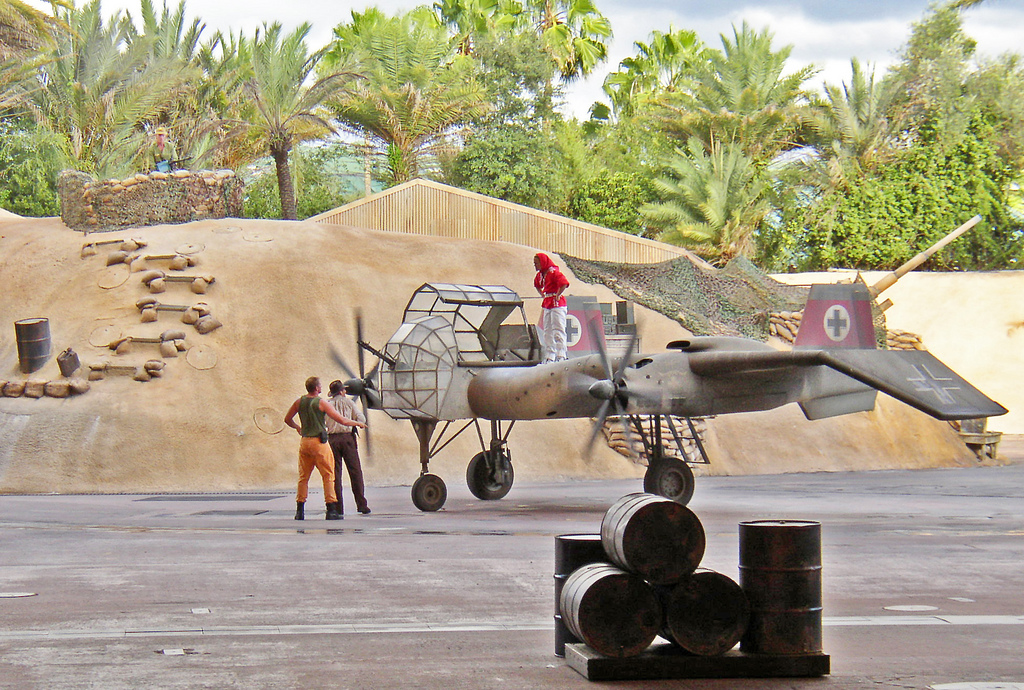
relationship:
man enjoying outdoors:
[284, 376, 371, 519] [7, 1, 1023, 686]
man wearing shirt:
[279, 372, 372, 520] [296, 387, 327, 437]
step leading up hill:
[76, 351, 167, 382] [6, 204, 989, 488]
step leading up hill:
[102, 320, 195, 359] [6, 204, 989, 488]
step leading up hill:
[140, 264, 220, 293] [6, 204, 989, 488]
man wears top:
[509, 235, 587, 382] [529, 248, 575, 303]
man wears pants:
[509, 235, 587, 382] [524, 295, 576, 367]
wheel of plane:
[401, 468, 462, 527] [309, 235, 1010, 519]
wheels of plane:
[460, 438, 709, 501] [339, 217, 1016, 507]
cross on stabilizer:
[820, 289, 862, 350] [790, 261, 899, 352]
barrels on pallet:
[567, 482, 745, 642] [550, 642, 838, 686]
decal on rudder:
[818, 296, 855, 340] [783, 268, 879, 351]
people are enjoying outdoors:
[149, 170, 841, 605] [76, 244, 176, 538]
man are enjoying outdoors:
[284, 376, 371, 519] [93, 449, 977, 690]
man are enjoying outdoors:
[284, 376, 371, 519] [544, 256, 895, 689]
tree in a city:
[287, 1, 504, 194] [5, 1, 991, 243]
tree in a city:
[855, 104, 970, 256] [8, 7, 991, 610]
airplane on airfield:
[328, 238, 992, 515] [6, 208, 992, 684]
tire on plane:
[407, 471, 453, 523] [330, 249, 992, 531]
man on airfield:
[284, 376, 371, 519] [6, 208, 992, 684]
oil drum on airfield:
[729, 513, 833, 656] [6, 208, 992, 684]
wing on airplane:
[688, 331, 989, 422] [328, 238, 992, 515]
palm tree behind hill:
[194, 18, 361, 222] [6, 204, 989, 488]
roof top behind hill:
[293, 173, 704, 267] [6, 204, 989, 488]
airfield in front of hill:
[6, 484, 992, 685] [6, 204, 989, 488]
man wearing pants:
[284, 376, 371, 519] [295, 439, 350, 509]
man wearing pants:
[284, 376, 371, 519] [291, 435, 352, 505]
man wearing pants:
[284, 376, 371, 519] [293, 439, 345, 509]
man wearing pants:
[284, 376, 371, 519] [287, 433, 348, 505]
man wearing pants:
[318, 379, 372, 514] [315, 430, 370, 517]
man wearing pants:
[314, 372, 381, 517] [323, 431, 378, 511]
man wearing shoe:
[284, 376, 371, 519] [323, 502, 347, 526]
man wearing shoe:
[284, 376, 371, 519] [286, 498, 319, 527]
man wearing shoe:
[284, 376, 371, 519] [323, 506, 356, 526]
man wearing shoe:
[284, 376, 371, 519] [287, 506, 309, 526]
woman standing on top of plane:
[519, 235, 582, 376] [369, 313, 920, 432]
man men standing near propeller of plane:
[284, 376, 371, 519] [387, 293, 910, 438]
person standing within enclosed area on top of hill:
[28, 105, 286, 199] [19, 203, 501, 310]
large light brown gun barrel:
[758, 269, 992, 462] [707, 274, 950, 435]